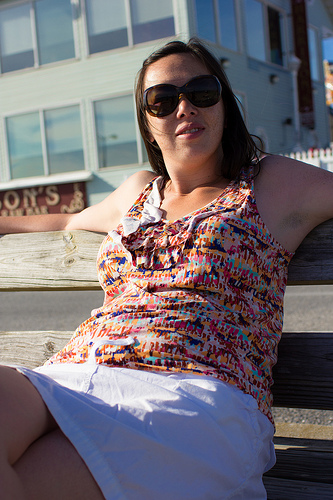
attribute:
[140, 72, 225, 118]
sunglasses — brown, oversized, dark, large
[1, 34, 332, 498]
girl — brunette, tan, relaxing, relaxed, content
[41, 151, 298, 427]
tank top — multi-colored, red, blue, colorful, sleeveless, summery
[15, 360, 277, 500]
mini-skirt — white, denim, wrinkled, summery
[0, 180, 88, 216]
sign — wooden, large, brown, red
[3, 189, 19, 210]
letter — cream color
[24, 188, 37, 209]
letter — cream color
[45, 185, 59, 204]
letter — cream color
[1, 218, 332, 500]
bench — wood, shady, wooden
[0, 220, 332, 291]
slat — wooden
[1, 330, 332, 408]
slat — wooden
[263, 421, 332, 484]
slat — wooden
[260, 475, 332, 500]
slat — wooden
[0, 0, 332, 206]
building — apartment, white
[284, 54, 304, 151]
lamppost — white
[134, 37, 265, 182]
hair — brown, long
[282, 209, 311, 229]
armpit — hairy, unshaved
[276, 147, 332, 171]
fence — picket, white